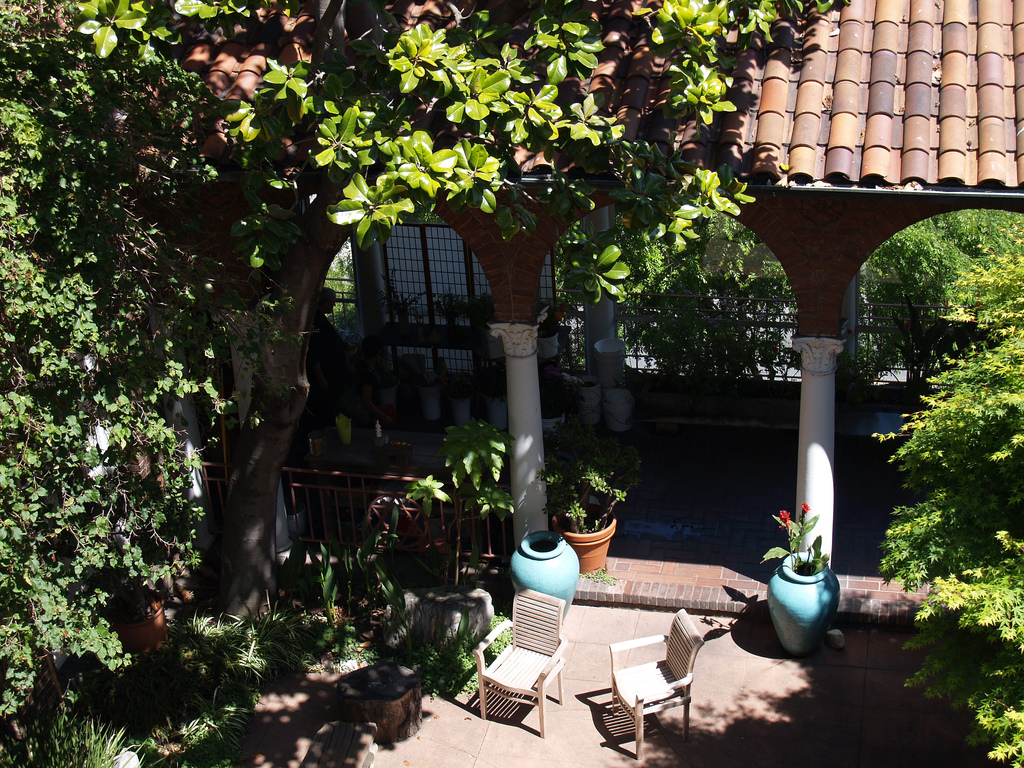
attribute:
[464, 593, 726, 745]
chairs — two white patio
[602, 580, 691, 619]
step — bricks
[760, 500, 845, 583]
flowers — red 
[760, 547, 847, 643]
pot — blue 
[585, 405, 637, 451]
purse — light brown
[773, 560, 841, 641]
pot — blue 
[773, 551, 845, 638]
vase — blue 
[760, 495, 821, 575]
flowers — red 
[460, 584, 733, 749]
chair — facing off 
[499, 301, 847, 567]
column — right white 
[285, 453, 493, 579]
railing — red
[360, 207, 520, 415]
window — white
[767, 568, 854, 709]
planter — blue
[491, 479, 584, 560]
planter — blue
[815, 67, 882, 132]
tile — brown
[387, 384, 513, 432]
pots — white, small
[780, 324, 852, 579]
column — white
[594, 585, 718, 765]
chair — white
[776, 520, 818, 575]
flowers — large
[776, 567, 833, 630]
planter — teal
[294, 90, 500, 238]
leaves — green 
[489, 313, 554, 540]
pillar — white , support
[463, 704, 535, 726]
shadow — cast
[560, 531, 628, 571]
planter — terracotta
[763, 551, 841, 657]
vase — blue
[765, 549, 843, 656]
pot — blue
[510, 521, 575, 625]
pot — blue, empty